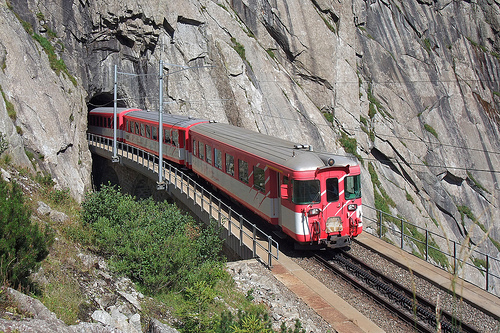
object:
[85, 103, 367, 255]
train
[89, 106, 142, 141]
train car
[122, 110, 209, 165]
train car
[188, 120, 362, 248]
train car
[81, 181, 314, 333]
bushes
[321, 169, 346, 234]
red door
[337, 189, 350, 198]
stripes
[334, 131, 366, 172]
plants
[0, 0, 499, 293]
cliff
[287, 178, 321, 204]
windows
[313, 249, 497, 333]
tracks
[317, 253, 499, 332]
gravel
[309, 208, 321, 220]
light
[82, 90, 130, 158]
train tunnel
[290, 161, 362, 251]
front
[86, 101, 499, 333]
railroad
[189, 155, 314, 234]
stripe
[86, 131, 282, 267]
railing